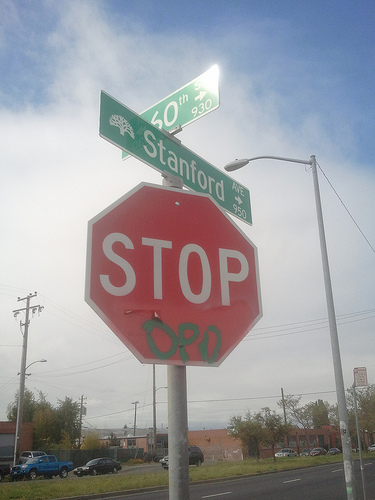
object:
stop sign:
[81, 180, 262, 371]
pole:
[165, 365, 189, 498]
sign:
[99, 89, 251, 226]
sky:
[198, 12, 336, 100]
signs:
[120, 63, 220, 163]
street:
[55, 472, 375, 499]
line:
[280, 474, 301, 484]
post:
[11, 289, 45, 463]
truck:
[8, 453, 74, 480]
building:
[254, 424, 330, 461]